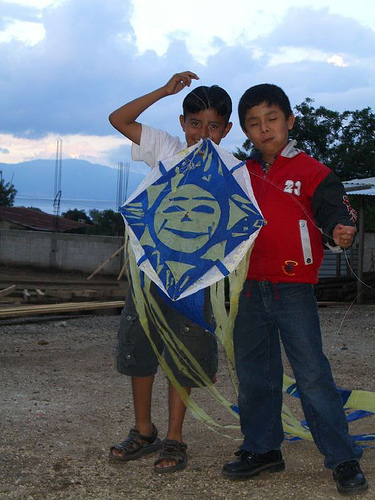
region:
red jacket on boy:
[229, 155, 339, 287]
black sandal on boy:
[152, 440, 186, 474]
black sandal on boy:
[106, 432, 147, 465]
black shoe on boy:
[215, 445, 281, 483]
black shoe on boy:
[327, 462, 365, 496]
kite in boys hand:
[117, 158, 241, 326]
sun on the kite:
[148, 179, 223, 282]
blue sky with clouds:
[18, 58, 110, 146]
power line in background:
[50, 135, 77, 270]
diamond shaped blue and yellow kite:
[91, 133, 270, 300]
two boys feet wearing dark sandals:
[93, 420, 194, 477]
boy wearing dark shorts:
[98, 267, 215, 480]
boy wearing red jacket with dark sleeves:
[235, 80, 357, 304]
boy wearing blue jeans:
[219, 447, 371, 496]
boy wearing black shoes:
[218, 442, 369, 495]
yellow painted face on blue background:
[141, 180, 227, 257]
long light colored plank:
[0, 291, 115, 313]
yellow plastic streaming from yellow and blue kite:
[120, 234, 235, 459]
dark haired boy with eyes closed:
[234, 84, 302, 153]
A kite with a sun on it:
[118, 135, 268, 306]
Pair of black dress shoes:
[220, 445, 370, 495]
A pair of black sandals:
[102, 427, 202, 480]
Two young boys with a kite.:
[82, 69, 371, 495]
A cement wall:
[1, 227, 124, 283]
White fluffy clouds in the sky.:
[3, 2, 374, 70]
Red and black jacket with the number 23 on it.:
[246, 151, 366, 291]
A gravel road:
[3, 331, 112, 498]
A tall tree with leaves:
[297, 97, 373, 182]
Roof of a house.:
[0, 197, 94, 234]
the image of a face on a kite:
[145, 183, 220, 251]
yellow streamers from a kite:
[124, 253, 216, 422]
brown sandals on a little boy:
[105, 424, 197, 481]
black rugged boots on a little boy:
[216, 446, 370, 496]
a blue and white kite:
[118, 142, 270, 299]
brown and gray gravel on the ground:
[6, 356, 104, 467]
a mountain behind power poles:
[4, 149, 110, 203]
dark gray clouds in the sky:
[27, 57, 95, 114]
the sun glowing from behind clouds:
[135, 3, 177, 43]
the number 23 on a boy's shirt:
[286, 171, 305, 204]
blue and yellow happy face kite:
[105, 128, 288, 314]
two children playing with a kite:
[95, 55, 367, 352]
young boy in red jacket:
[234, 70, 363, 311]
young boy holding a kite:
[96, 64, 269, 316]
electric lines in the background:
[48, 133, 135, 228]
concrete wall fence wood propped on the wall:
[18, 221, 126, 286]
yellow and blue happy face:
[140, 175, 229, 264]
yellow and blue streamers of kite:
[130, 310, 373, 438]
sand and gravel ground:
[22, 378, 97, 469]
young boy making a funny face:
[231, 70, 368, 293]